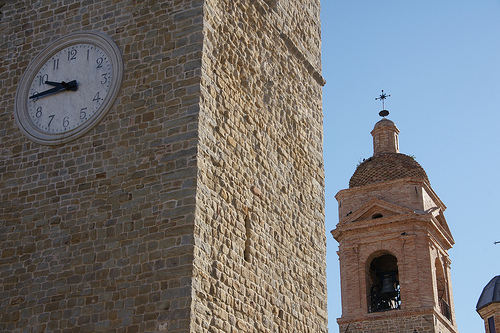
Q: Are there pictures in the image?
A: No, there are no pictures.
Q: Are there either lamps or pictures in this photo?
A: No, there are no pictures or lamps.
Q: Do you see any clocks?
A: Yes, there is a clock.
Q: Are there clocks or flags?
A: Yes, there is a clock.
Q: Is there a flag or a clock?
A: Yes, there is a clock.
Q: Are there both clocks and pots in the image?
A: No, there is a clock but no pots.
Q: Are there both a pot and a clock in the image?
A: No, there is a clock but no pots.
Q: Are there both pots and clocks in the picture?
A: No, there is a clock but no pots.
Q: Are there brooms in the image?
A: No, there are no brooms.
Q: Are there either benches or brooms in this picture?
A: No, there are no brooms or benches.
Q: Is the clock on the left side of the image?
A: Yes, the clock is on the left of the image.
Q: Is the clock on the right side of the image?
A: No, the clock is on the left of the image.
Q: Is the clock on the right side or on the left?
A: The clock is on the left of the image.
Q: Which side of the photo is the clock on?
A: The clock is on the left of the image.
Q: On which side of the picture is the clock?
A: The clock is on the left of the image.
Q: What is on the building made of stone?
A: The clock is on the clock tower.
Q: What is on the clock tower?
A: The clock is on the clock tower.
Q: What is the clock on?
A: The clock is on the clock tower.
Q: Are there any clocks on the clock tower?
A: Yes, there is a clock on the clock tower.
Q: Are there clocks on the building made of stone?
A: Yes, there is a clock on the clock tower.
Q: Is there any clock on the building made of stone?
A: Yes, there is a clock on the clock tower.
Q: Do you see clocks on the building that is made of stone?
A: Yes, there is a clock on the clock tower.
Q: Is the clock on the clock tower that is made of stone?
A: Yes, the clock is on the clock tower.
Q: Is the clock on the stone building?
A: Yes, the clock is on the clock tower.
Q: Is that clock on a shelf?
A: No, the clock is on the clock tower.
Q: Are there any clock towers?
A: Yes, there is a clock tower.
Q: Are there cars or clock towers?
A: Yes, there is a clock tower.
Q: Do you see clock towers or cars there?
A: Yes, there is a clock tower.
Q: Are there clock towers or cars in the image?
A: Yes, there is a clock tower.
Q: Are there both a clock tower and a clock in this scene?
A: Yes, there are both a clock tower and a clock.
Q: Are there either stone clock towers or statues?
A: Yes, there is a stone clock tower.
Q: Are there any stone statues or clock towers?
A: Yes, there is a stone clock tower.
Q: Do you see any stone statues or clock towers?
A: Yes, there is a stone clock tower.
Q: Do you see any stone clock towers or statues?
A: Yes, there is a stone clock tower.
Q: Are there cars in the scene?
A: No, there are no cars.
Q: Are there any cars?
A: No, there are no cars.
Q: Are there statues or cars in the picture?
A: No, there are no cars or statues.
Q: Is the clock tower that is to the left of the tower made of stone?
A: Yes, the clock tower is made of stone.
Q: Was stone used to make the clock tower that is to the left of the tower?
A: Yes, the clock tower is made of stone.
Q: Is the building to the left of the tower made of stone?
A: Yes, the clock tower is made of stone.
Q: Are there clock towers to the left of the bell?
A: Yes, there is a clock tower to the left of the bell.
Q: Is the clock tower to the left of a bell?
A: Yes, the clock tower is to the left of a bell.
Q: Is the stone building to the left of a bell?
A: Yes, the clock tower is to the left of a bell.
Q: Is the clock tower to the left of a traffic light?
A: No, the clock tower is to the left of a bell.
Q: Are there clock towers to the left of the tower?
A: Yes, there is a clock tower to the left of the tower.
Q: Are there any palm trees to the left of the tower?
A: No, there is a clock tower to the left of the tower.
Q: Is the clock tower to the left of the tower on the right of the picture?
A: Yes, the clock tower is to the left of the tower.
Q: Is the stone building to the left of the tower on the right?
A: Yes, the clock tower is to the left of the tower.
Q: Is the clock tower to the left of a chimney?
A: No, the clock tower is to the left of the tower.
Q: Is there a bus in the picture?
A: No, there are no buses.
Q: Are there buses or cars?
A: No, there are no buses or cars.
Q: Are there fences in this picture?
A: No, there are no fences.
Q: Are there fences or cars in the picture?
A: No, there are no fences or cars.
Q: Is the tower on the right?
A: Yes, the tower is on the right of the image.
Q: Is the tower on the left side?
A: No, the tower is on the right of the image.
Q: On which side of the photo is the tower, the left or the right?
A: The tower is on the right of the image.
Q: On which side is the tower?
A: The tower is on the right of the image.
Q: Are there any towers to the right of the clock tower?
A: Yes, there is a tower to the right of the clock tower.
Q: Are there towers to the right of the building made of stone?
A: Yes, there is a tower to the right of the clock tower.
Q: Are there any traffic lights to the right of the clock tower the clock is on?
A: No, there is a tower to the right of the clock tower.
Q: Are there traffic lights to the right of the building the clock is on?
A: No, there is a tower to the right of the clock tower.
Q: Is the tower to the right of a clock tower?
A: Yes, the tower is to the right of a clock tower.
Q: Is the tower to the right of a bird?
A: No, the tower is to the right of a clock tower.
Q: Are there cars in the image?
A: No, there are no cars.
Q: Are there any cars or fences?
A: No, there are no cars or fences.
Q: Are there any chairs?
A: No, there are no chairs.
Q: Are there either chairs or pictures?
A: No, there are no chairs or pictures.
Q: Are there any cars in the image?
A: No, there are no cars.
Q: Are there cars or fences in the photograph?
A: No, there are no cars or fences.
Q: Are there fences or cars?
A: No, there are no cars or fences.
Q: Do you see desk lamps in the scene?
A: No, there are no desk lamps.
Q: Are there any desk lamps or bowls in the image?
A: No, there are no desk lamps or bowls.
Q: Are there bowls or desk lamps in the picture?
A: No, there are no desk lamps or bowls.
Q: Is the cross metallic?
A: Yes, the cross is metallic.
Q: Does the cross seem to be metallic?
A: Yes, the cross is metallic.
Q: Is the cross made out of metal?
A: Yes, the cross is made of metal.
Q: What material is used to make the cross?
A: The cross is made of metal.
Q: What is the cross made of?
A: The cross is made of metal.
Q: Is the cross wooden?
A: No, the cross is metallic.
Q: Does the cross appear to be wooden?
A: No, the cross is metallic.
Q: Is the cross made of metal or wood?
A: The cross is made of metal.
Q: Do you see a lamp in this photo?
A: No, there are no lamps.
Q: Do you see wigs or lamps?
A: No, there are no lamps or wigs.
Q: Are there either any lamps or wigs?
A: No, there are no lamps or wigs.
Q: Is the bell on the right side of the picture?
A: Yes, the bell is on the right of the image.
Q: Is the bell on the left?
A: No, the bell is on the right of the image.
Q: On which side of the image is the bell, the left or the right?
A: The bell is on the right of the image.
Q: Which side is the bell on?
A: The bell is on the right of the image.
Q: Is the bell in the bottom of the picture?
A: Yes, the bell is in the bottom of the image.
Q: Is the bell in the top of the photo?
A: No, the bell is in the bottom of the image.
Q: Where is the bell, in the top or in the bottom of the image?
A: The bell is in the bottom of the image.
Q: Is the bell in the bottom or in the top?
A: The bell is in the bottom of the image.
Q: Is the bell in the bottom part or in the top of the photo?
A: The bell is in the bottom of the image.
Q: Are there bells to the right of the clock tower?
A: Yes, there is a bell to the right of the clock tower.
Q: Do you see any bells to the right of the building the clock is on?
A: Yes, there is a bell to the right of the clock tower.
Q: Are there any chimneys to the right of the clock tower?
A: No, there is a bell to the right of the clock tower.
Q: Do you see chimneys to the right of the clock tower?
A: No, there is a bell to the right of the clock tower.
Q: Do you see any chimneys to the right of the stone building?
A: No, there is a bell to the right of the clock tower.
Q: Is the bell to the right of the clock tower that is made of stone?
A: Yes, the bell is to the right of the clock tower.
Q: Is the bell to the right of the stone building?
A: Yes, the bell is to the right of the clock tower.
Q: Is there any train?
A: No, there are no trains.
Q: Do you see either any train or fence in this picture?
A: No, there are no trains or fences.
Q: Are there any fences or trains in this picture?
A: No, there are no trains or fences.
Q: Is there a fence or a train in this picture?
A: No, there are no trains or fences.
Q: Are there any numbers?
A: Yes, there are numbers.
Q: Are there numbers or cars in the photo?
A: Yes, there are numbers.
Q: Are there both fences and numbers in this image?
A: No, there are numbers but no fences.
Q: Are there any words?
A: No, there are no words.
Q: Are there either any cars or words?
A: No, there are no words or cars.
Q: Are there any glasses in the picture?
A: No, there are no glasses.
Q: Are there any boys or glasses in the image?
A: No, there are no glasses or boys.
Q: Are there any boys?
A: No, there are no boys.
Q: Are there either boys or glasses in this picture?
A: No, there are no boys or glasses.